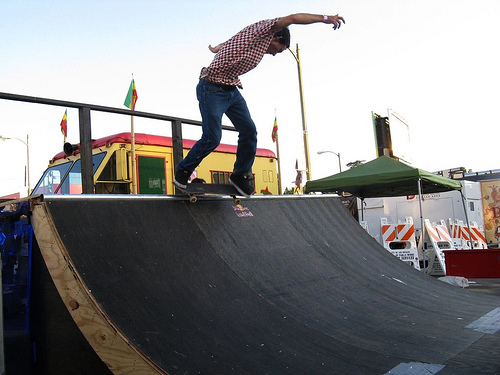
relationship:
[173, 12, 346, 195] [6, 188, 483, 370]
man on ramp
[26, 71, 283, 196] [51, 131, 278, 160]
food truck has top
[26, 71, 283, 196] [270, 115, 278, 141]
food truck has flag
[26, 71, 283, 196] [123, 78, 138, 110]
food truck has flag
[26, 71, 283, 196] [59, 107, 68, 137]
food truck has flag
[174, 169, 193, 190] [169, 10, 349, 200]
feet of person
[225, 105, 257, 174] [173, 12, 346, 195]
leg of man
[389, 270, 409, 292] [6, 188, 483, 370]
white mark on ramp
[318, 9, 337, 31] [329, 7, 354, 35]
watch to hand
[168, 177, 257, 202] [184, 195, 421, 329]
skateboard on top of ramp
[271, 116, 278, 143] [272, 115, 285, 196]
flag on pole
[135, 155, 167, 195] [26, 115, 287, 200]
window on side of truck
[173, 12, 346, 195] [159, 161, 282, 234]
man riding skateboard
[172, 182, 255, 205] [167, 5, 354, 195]
skateboard of man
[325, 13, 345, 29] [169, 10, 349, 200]
hand of person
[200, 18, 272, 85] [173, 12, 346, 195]
shirt of man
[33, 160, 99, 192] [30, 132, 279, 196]
windows on front of food truck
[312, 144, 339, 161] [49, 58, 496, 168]
light in background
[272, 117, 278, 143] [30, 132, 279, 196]
flag on food truck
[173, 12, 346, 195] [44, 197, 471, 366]
man on ramp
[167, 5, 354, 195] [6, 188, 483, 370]
man skateboarding up ramp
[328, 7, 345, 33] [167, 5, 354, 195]
arm of man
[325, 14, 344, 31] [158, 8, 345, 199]
hand of man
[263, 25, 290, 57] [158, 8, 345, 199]
head of man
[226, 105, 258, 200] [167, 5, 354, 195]
leg of man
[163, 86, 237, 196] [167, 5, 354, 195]
leg of man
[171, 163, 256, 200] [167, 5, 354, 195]
feet of man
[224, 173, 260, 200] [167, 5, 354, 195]
foot of man